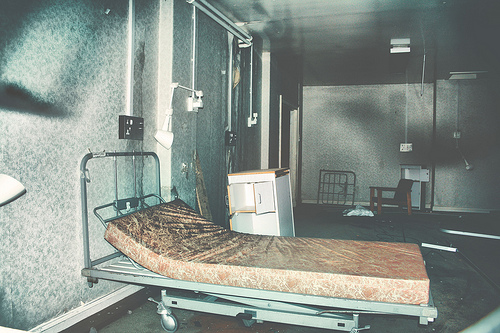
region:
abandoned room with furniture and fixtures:
[5, 1, 490, 326]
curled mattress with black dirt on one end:
[101, 190, 432, 307]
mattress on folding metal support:
[80, 150, 436, 330]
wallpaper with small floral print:
[5, 1, 260, 327]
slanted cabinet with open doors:
[220, 161, 295, 236]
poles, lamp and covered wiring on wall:
[115, 1, 255, 146]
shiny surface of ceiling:
[221, 0, 491, 82]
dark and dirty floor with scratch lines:
[77, 197, 492, 327]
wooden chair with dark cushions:
[365, 176, 420, 216]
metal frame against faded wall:
[312, 165, 357, 210]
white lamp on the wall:
[153, 75, 185, 154]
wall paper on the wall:
[1, 0, 254, 322]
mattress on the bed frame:
[95, 187, 447, 324]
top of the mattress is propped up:
[96, 189, 251, 289]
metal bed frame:
[63, 132, 441, 326]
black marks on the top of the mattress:
[111, 198, 246, 260]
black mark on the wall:
[3, 72, 68, 124]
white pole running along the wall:
[118, 3, 141, 117]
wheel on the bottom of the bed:
[153, 303, 176, 332]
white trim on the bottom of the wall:
[19, 283, 147, 330]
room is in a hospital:
[156, 57, 453, 299]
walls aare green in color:
[38, 39, 153, 158]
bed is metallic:
[81, 234, 270, 332]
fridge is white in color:
[228, 167, 307, 241]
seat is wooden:
[358, 162, 433, 207]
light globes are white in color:
[163, 24, 195, 177]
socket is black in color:
[113, 114, 158, 149]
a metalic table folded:
[318, 159, 359, 205]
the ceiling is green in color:
[307, 14, 354, 54]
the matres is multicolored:
[145, 199, 330, 262]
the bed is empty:
[112, 191, 427, 291]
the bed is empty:
[201, 236, 420, 292]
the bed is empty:
[106, 201, 405, 316]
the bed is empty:
[100, 191, 415, 318]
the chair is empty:
[352, 178, 421, 213]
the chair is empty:
[356, 171, 416, 212]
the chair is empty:
[360, 159, 417, 211]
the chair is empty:
[360, 166, 415, 223]